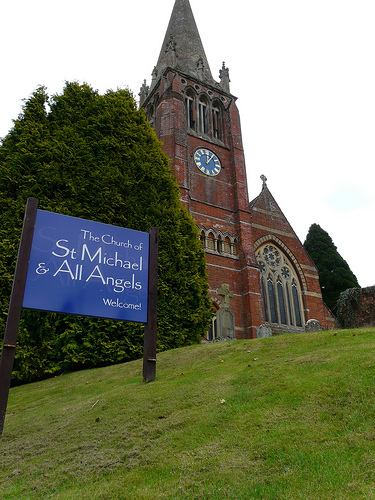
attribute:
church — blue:
[130, 12, 344, 326]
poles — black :
[6, 188, 169, 383]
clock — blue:
[194, 147, 220, 174]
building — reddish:
[137, 1, 345, 336]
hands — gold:
[205, 149, 217, 165]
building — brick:
[73, 0, 342, 354]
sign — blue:
[0, 196, 158, 433]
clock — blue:
[177, 129, 244, 179]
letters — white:
[35, 228, 143, 311]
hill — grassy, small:
[1, 326, 373, 499]